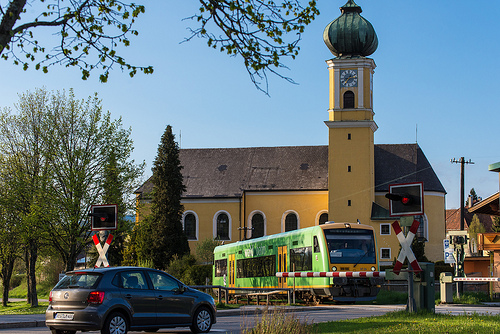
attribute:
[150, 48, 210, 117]
sky — blue, clear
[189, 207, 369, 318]
train — green, short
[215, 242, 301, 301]
door — yellow, closed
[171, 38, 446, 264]
building — yellow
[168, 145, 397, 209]
roof — brown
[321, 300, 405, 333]
grass — green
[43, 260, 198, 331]
car — gray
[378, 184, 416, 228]
light — red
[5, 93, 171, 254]
trees — green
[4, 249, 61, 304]
trunk — brown